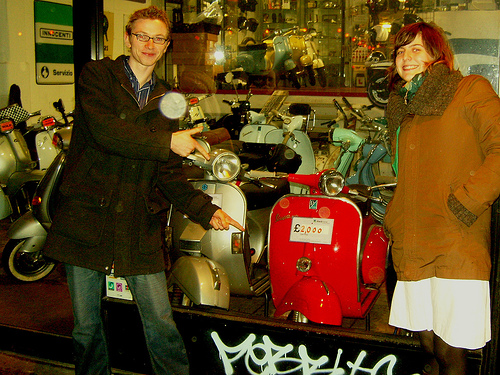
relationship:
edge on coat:
[402, 272, 469, 284] [381, 64, 498, 281]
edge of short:
[387, 306, 427, 336] [395, 298, 437, 333]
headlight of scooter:
[204, 147, 245, 187] [189, 90, 310, 300]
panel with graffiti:
[167, 305, 423, 368] [205, 332, 395, 372]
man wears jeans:
[37, 7, 241, 356] [64, 248, 180, 360]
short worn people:
[387, 276, 491, 349] [383, 21, 498, 374]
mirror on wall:
[163, 0, 404, 98] [163, 10, 410, 125]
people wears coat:
[383, 21, 498, 374] [381, 64, 498, 281]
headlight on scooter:
[320, 167, 345, 196] [269, 167, 388, 329]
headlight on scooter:
[207, 148, 242, 183] [163, 138, 295, 318]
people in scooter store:
[383, 21, 498, 374] [5, 0, 486, 374]